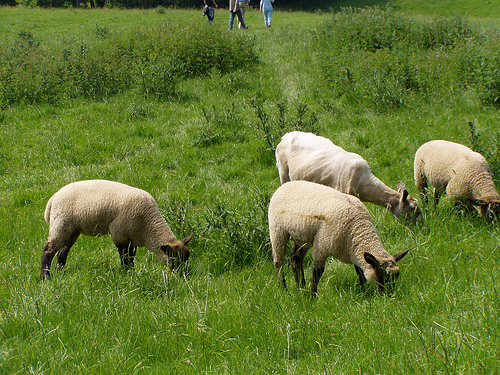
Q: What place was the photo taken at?
A: It was taken at the field.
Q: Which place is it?
A: It is a field.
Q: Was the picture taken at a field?
A: Yes, it was taken in a field.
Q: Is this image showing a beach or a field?
A: It is showing a field.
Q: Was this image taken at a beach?
A: No, the picture was taken in a field.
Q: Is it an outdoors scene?
A: Yes, it is outdoors.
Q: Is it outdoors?
A: Yes, it is outdoors.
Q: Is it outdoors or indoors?
A: It is outdoors.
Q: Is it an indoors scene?
A: No, it is outdoors.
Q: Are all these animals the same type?
A: Yes, all the animals are sheep.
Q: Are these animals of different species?
A: No, all the animals are sheep.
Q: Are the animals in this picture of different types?
A: No, all the animals are sheep.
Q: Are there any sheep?
A: Yes, there is a sheep.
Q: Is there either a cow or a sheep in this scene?
A: Yes, there is a sheep.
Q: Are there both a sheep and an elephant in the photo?
A: No, there is a sheep but no elephants.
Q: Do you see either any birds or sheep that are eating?
A: Yes, the sheep is eating.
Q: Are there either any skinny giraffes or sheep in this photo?
A: Yes, there is a skinny sheep.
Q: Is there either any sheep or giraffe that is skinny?
A: Yes, the sheep is skinny.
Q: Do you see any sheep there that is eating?
A: Yes, there is a sheep that is eating.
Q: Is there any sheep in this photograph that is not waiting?
A: Yes, there is a sheep that is eating.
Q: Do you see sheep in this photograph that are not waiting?
A: Yes, there is a sheep that is eating .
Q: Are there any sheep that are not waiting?
A: Yes, there is a sheep that is eating.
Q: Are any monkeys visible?
A: No, there are no monkeys.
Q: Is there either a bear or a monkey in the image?
A: No, there are no monkeys or bears.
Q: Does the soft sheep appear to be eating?
A: Yes, the sheep is eating.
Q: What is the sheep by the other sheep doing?
A: The sheep is eating.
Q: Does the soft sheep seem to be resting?
A: No, the sheep is eating.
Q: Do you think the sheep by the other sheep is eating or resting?
A: The sheep is eating.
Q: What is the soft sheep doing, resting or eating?
A: The sheep is eating.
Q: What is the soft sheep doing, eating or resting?
A: The sheep is eating.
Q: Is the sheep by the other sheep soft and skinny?
A: Yes, the sheep is soft and skinny.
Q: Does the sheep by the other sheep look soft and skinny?
A: Yes, the sheep is soft and skinny.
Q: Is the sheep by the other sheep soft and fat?
A: No, the sheep is soft but skinny.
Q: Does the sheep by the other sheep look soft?
A: Yes, the sheep is soft.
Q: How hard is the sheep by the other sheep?
A: The sheep is soft.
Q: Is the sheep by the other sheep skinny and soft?
A: Yes, the sheep is skinny and soft.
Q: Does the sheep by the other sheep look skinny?
A: Yes, the sheep is skinny.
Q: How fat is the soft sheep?
A: The sheep is skinny.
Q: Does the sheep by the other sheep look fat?
A: No, the sheep is skinny.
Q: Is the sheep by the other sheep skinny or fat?
A: The sheep is skinny.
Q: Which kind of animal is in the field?
A: The animal is a sheep.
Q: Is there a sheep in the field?
A: Yes, there is a sheep in the field.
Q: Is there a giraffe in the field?
A: No, there is a sheep in the field.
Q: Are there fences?
A: No, there are no fences.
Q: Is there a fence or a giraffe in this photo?
A: No, there are no fences or giraffes.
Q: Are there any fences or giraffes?
A: No, there are no fences or giraffes.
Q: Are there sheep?
A: Yes, there is a sheep.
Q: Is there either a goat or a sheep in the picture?
A: Yes, there is a sheep.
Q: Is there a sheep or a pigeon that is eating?
A: Yes, the sheep is eating.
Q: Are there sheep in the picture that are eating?
A: Yes, there is a sheep that is eating.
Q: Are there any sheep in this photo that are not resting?
A: Yes, there is a sheep that is eating.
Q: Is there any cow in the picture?
A: No, there are no cows.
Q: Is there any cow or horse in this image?
A: No, there are no cows or horses.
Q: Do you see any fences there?
A: No, there are no fences.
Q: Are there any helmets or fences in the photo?
A: No, there are no fences or helmets.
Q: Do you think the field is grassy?
A: Yes, the field is grassy.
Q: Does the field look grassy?
A: Yes, the field is grassy.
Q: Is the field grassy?
A: Yes, the field is grassy.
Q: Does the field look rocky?
A: No, the field is grassy.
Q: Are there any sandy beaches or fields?
A: No, there is a field but it is grassy.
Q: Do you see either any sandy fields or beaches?
A: No, there is a field but it is grassy.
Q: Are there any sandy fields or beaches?
A: No, there is a field but it is grassy.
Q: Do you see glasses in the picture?
A: No, there are no glasses.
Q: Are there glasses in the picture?
A: No, there are no glasses.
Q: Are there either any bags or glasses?
A: No, there are no glasses or bags.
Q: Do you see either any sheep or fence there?
A: Yes, there is a sheep.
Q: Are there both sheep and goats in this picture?
A: No, there is a sheep but no goats.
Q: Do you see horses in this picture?
A: No, there are no horses.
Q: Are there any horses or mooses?
A: No, there are no horses or mooses.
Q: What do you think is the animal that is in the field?
A: The animal is a sheep.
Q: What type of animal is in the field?
A: The animal is a sheep.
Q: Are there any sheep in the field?
A: Yes, there is a sheep in the field.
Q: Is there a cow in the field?
A: No, there is a sheep in the field.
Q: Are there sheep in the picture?
A: Yes, there is a sheep.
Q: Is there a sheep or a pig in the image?
A: Yes, there is a sheep.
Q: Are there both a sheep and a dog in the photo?
A: No, there is a sheep but no dogs.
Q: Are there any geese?
A: No, there are no geese.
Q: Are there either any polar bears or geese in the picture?
A: No, there are no geese or polar bears.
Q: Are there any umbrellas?
A: No, there are no umbrellas.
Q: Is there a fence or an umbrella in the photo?
A: No, there are no umbrellas or fences.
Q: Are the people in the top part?
A: Yes, the people are in the top of the image.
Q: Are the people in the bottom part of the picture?
A: No, the people are in the top of the image.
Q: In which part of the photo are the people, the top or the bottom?
A: The people are in the top of the image.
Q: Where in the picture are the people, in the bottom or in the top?
A: The people are in the top of the image.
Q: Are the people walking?
A: Yes, the people are walking.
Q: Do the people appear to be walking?
A: Yes, the people are walking.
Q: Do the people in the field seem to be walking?
A: Yes, the people are walking.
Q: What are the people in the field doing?
A: The people are walking.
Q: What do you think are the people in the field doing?
A: The people are walking.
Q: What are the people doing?
A: The people are walking.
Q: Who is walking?
A: The people are walking.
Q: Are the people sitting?
A: No, the people are walking.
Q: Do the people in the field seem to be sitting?
A: No, the people are walking.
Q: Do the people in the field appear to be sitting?
A: No, the people are walking.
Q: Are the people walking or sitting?
A: The people are walking.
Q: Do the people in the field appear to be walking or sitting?
A: The people are walking.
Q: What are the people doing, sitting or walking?
A: The people are walking.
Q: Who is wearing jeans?
A: The people are wearing jeans.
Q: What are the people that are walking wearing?
A: The people are wearing jeans.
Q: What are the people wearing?
A: The people are wearing jeans.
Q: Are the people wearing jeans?
A: Yes, the people are wearing jeans.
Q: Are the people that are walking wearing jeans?
A: Yes, the people are wearing jeans.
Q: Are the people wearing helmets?
A: No, the people are wearing jeans.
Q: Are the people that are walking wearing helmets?
A: No, the people are wearing jeans.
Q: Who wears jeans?
A: The people wear jeans.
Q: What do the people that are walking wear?
A: The people wear jeans.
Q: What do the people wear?
A: The people wear jeans.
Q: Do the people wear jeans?
A: Yes, the people wear jeans.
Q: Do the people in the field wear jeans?
A: Yes, the people wear jeans.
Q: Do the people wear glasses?
A: No, the people wear jeans.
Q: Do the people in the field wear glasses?
A: No, the people wear jeans.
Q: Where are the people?
A: The people are in the field.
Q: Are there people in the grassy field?
A: Yes, there are people in the field.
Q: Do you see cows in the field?
A: No, there are people in the field.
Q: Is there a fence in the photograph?
A: No, there are no fences.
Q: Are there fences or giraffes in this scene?
A: No, there are no fences or giraffes.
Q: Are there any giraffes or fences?
A: No, there are no fences or giraffes.